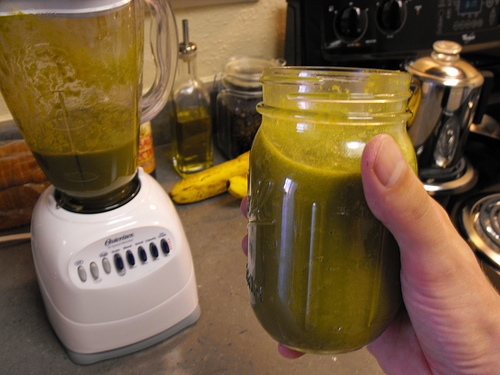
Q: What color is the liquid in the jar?
A: Green.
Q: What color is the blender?
A: White.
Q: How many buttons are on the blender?
A: Eight.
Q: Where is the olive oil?
A: In the background behind the blender.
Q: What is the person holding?
A: A Jar.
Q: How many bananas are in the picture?
A: Two.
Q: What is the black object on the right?
A: A Stove.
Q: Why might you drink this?
A: To be healthy.